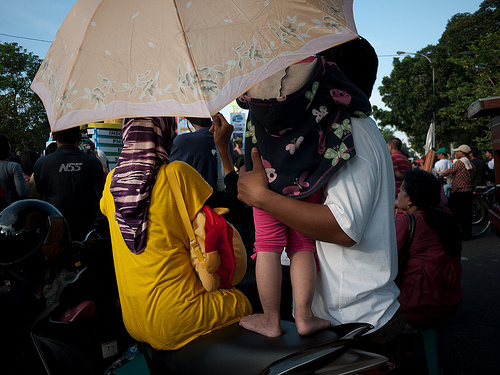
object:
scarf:
[109, 116, 170, 256]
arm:
[194, 229, 222, 255]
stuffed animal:
[189, 205, 247, 293]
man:
[237, 34, 406, 374]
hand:
[237, 147, 269, 213]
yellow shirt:
[99, 161, 252, 351]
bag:
[165, 163, 248, 292]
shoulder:
[154, 160, 199, 174]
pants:
[250, 187, 321, 271]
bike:
[0, 198, 110, 374]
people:
[394, 169, 463, 330]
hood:
[243, 55, 325, 138]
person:
[433, 144, 473, 241]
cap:
[452, 144, 471, 153]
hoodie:
[235, 56, 371, 208]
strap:
[164, 162, 205, 261]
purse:
[197, 260, 221, 292]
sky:
[368, 17, 452, 53]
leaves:
[225, 60, 236, 66]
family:
[99, 33, 405, 352]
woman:
[394, 168, 461, 330]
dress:
[395, 212, 462, 330]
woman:
[98, 117, 253, 352]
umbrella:
[28, 0, 362, 138]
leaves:
[177, 62, 228, 101]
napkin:
[459, 157, 473, 171]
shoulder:
[453, 159, 466, 164]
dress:
[99, 160, 252, 350]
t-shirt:
[291, 117, 402, 337]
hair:
[55, 126, 80, 144]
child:
[235, 56, 372, 317]